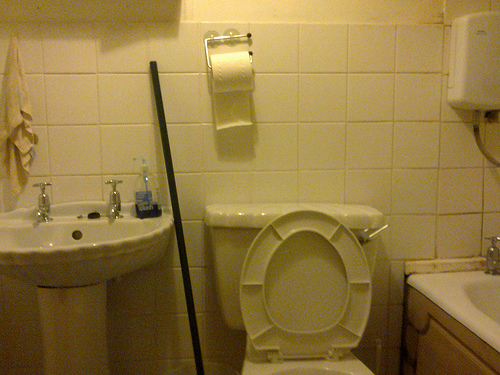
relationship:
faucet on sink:
[32, 182, 55, 223] [1, 196, 176, 373]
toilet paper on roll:
[203, 52, 258, 133] [200, 31, 260, 72]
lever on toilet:
[358, 221, 395, 245] [201, 198, 387, 375]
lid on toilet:
[237, 210, 372, 360] [201, 198, 387, 375]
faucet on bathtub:
[480, 231, 495, 275] [401, 269, 500, 374]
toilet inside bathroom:
[201, 198, 387, 375] [7, 0, 497, 373]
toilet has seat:
[201, 198, 387, 375] [238, 208, 373, 359]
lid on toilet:
[237, 208, 375, 363] [199, 192, 392, 374]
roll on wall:
[204, 50, 244, 228] [0, 23, 497, 373]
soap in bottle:
[137, 202, 161, 217] [131, 155, 163, 218]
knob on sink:
[28, 176, 55, 208] [4, 208, 169, 373]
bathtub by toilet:
[400, 250, 472, 370] [214, 185, 387, 373]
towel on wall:
[4, 33, 49, 193] [22, 42, 102, 129]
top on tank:
[202, 202, 387, 235] [208, 224, 383, 331]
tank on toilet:
[208, 224, 383, 331] [201, 198, 387, 375]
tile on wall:
[349, 72, 395, 124] [19, 2, 489, 247]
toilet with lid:
[230, 202, 382, 374] [237, 208, 375, 363]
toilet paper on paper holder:
[209, 50, 255, 131] [203, 32, 253, 69]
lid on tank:
[202, 198, 388, 231] [204, 202, 387, 333]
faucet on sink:
[30, 180, 55, 227] [1, 196, 176, 373]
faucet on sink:
[101, 176, 124, 226] [1, 196, 176, 373]